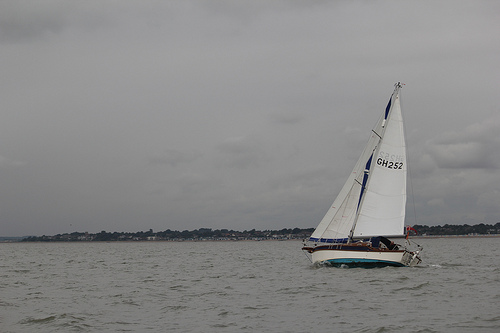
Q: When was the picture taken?
A: In the evening.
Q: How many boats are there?
A: 1.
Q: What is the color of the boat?
A: White.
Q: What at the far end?
A: Trees.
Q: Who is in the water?
A: No one.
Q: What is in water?
A: Ripples.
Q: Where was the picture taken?
A: Sailing in the bay.